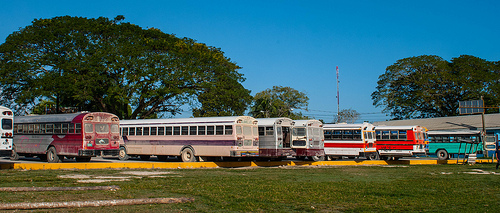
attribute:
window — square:
[135, 125, 143, 136]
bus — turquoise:
[426, 129, 484, 160]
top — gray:
[424, 128, 484, 134]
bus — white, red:
[373, 119, 431, 159]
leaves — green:
[404, 68, 429, 89]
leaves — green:
[77, 43, 129, 73]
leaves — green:
[425, 61, 455, 85]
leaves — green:
[452, 61, 476, 89]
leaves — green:
[213, 67, 241, 104]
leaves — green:
[165, 51, 207, 66]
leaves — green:
[115, 74, 158, 94]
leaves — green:
[105, 27, 146, 56]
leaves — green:
[94, 81, 128, 101]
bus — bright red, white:
[370, 119, 435, 168]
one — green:
[427, 127, 484, 157]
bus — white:
[324, 122, 377, 162]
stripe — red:
[316, 141, 381, 150]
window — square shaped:
[153, 124, 178, 138]